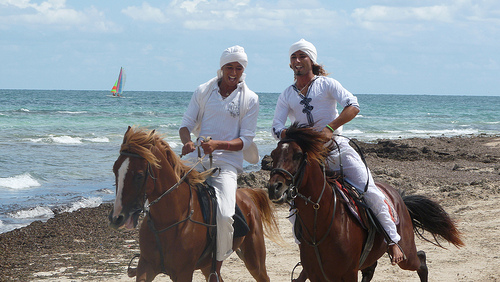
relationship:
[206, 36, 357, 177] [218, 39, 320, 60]
riders wearing turbans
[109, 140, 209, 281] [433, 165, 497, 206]
horse on beach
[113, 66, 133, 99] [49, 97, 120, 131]
sailboat on ocean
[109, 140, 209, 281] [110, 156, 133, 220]
horse has white stripe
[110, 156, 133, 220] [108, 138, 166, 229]
white stripe on horses head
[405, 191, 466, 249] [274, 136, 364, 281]
tail on side of horse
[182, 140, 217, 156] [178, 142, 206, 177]
hands holding on to reins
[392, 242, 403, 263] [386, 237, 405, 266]
foot inside of stirrup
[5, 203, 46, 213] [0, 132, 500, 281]
seaweed along beach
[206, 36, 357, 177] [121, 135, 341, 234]
riders riding horses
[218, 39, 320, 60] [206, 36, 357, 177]
turbans on riders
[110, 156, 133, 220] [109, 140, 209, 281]
white stripe on horse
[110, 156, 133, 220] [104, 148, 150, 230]
white stripe on face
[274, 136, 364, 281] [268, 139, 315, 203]
horse has dark face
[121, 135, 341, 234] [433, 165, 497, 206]
horses on beach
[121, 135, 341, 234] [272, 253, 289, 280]
horses running on sand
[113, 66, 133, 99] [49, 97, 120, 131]
sailboat in ocean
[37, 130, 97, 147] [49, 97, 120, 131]
waves in ocean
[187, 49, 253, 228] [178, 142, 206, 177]
man holding reins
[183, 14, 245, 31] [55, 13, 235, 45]
clouds are in sky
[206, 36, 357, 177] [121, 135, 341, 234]
riders are on top of horses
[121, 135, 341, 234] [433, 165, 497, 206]
horses are on beach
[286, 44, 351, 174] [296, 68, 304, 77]
man has facial hair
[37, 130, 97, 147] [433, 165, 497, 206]
waves crashing in to beach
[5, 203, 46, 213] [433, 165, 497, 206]
seaweed on beach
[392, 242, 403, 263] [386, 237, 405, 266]
foot in stirrup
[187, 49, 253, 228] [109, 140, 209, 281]
man riding horse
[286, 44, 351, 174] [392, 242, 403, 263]
man has barefoot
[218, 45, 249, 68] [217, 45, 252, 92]
turban on top of head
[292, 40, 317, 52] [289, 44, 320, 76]
turban on top of head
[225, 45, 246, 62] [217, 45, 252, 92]
turban on top of head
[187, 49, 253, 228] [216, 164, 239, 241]
man wearing pants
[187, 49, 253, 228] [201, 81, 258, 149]
man wearing shirt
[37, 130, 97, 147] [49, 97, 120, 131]
waves breaking in ocean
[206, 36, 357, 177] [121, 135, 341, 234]
riders on horses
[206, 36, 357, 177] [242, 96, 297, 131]
riders wearing white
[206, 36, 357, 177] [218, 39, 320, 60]
riders in turbans